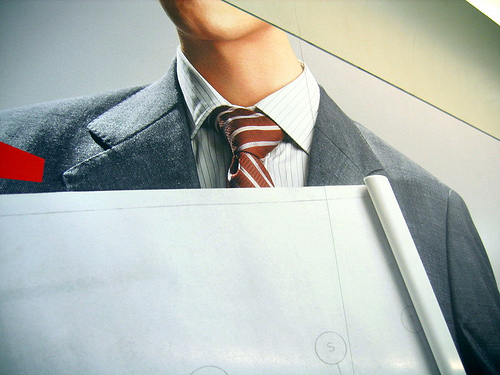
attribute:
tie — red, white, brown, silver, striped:
[205, 105, 285, 187]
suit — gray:
[1, 55, 500, 374]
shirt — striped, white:
[177, 46, 322, 186]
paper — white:
[1, 175, 467, 374]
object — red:
[1, 142, 45, 182]